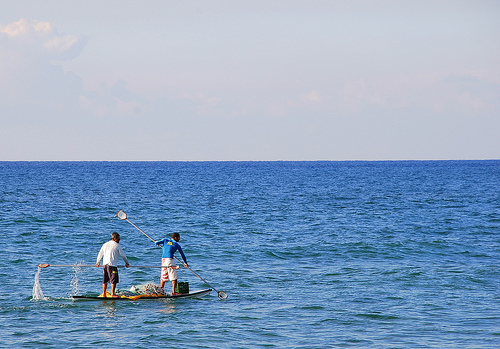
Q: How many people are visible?
A: Two.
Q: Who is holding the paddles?
A: The men.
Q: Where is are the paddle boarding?
A: In the ocean.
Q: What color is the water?
A: Blue.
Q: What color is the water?
A: Blue.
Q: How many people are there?
A: Two.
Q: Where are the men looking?
A: Down.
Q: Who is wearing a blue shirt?
A: Man on the right.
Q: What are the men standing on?
A: Paddleboard.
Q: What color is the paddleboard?
A: Green.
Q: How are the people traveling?
A: On a paddleboard.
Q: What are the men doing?
A: Stand up paddle boarding.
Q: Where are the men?
A: On a board in the sea.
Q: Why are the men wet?
A: They're on a paddleboard.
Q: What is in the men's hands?
A: Oars.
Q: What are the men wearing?
A: Shorts and t shirts.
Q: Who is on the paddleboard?
A: Two men.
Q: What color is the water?
A: Blue.